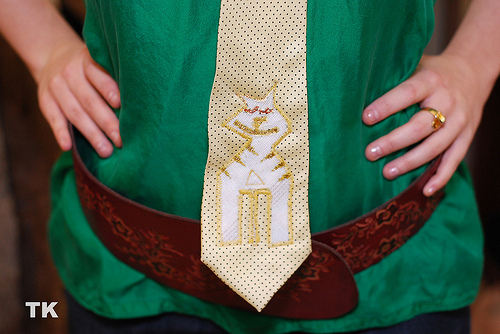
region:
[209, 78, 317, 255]
awesome yellow cat tie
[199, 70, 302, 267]
cat is square and smiling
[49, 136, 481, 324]
brown leather belt with flower detail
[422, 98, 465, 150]
yellow ring with yellow jewel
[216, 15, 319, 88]
tie has small dots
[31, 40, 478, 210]
person has hands on hips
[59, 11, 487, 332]
person wearing emerald green shirt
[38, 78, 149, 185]
person bites fingernails short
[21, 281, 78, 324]
TK logo in the corner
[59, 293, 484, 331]
person wearing blue jeans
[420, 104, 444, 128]
a silvery ring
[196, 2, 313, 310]
a funny tie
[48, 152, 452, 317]
a nice brown belt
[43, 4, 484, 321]
a green top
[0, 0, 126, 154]
a person's hand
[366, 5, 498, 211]
a person's hand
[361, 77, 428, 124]
a person's finger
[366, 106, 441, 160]
a person's finger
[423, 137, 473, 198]
a person's finger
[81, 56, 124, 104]
a person's finger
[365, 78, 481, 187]
woman is wearing a ring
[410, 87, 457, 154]
the ring is gold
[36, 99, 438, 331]
the belt is brown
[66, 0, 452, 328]
the shirt is green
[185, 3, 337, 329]
woman is wearing a tie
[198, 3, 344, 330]
the tie is yellow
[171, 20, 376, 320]
the tie has a cat on it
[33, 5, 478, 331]
hands on the waist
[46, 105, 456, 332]
woman is wearing a belt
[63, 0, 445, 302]
woman is wearing a shirt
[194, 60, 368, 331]
a M Cat tie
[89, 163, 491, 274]
a blet that should not be worn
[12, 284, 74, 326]
TK written in there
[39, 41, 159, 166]
a hand with no jewelery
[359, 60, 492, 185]
a hand with a ring on it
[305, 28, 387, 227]
a green shirt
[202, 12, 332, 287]
a tie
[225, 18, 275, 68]
black polka dots on the tie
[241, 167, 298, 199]
a small triangle that is in the cat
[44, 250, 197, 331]
Jeans that the person is wearing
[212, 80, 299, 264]
a white and gold cat insignia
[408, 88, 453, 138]
a gold ring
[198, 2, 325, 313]
a gold dotted tie with a cat design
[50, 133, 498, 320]
a crafted leather belt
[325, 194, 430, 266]
a floral design on the leather belt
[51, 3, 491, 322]
a green t-shirt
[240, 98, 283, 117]
the cat's two red eyes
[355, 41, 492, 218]
the person's left hand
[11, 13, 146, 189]
the person's right hand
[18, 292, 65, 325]
the letters T and K